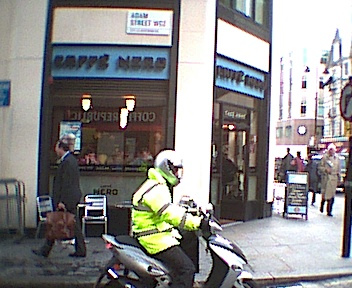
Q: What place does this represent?
A: It represents the coffee shop.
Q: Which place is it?
A: It is a coffee shop.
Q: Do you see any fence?
A: No, there are no fences.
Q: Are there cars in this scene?
A: No, there are no cars.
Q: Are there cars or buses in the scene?
A: No, there are no cars or buses.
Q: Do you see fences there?
A: No, there are no fences.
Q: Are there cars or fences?
A: No, there are no fences or cars.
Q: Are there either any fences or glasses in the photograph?
A: No, there are no fences or glasses.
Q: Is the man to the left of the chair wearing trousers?
A: Yes, the man is wearing trousers.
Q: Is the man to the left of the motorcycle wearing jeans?
A: No, the man is wearing trousers.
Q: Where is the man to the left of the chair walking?
A: The man is walking on the sidewalk.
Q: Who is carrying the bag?
A: The man is carrying the bag.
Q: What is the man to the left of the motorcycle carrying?
A: The man is carrying a bag.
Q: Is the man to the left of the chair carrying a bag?
A: Yes, the man is carrying a bag.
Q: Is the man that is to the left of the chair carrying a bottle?
A: No, the man is carrying a bag.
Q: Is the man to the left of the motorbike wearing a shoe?
A: Yes, the man is wearing a shoe.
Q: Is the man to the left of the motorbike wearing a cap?
A: No, the man is wearing a shoe.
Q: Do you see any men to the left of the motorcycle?
A: Yes, there is a man to the left of the motorcycle.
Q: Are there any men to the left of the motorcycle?
A: Yes, there is a man to the left of the motorcycle.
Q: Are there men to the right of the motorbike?
A: No, the man is to the left of the motorbike.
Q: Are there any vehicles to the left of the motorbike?
A: No, there is a man to the left of the motorbike.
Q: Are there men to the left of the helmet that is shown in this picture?
A: Yes, there is a man to the left of the helmet.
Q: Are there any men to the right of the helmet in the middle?
A: No, the man is to the left of the helmet.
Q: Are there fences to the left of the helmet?
A: No, there is a man to the left of the helmet.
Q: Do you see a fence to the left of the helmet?
A: No, there is a man to the left of the helmet.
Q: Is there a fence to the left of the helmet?
A: No, there is a man to the left of the helmet.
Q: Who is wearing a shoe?
A: The man is wearing a shoe.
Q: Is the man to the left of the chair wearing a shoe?
A: Yes, the man is wearing a shoe.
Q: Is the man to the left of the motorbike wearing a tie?
A: No, the man is wearing a shoe.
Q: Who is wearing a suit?
A: The man is wearing a suit.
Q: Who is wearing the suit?
A: The man is wearing a suit.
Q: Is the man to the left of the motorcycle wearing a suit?
A: Yes, the man is wearing a suit.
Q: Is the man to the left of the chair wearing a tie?
A: No, the man is wearing a suit.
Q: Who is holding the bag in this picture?
A: The man is holding the bag.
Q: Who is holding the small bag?
A: The man is holding the bag.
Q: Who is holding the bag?
A: The man is holding the bag.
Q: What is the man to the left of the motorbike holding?
A: The man is holding the bag.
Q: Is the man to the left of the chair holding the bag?
A: Yes, the man is holding the bag.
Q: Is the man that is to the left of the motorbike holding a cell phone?
A: No, the man is holding the bag.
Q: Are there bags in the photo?
A: Yes, there is a bag.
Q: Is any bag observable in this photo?
A: Yes, there is a bag.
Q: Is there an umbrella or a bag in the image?
A: Yes, there is a bag.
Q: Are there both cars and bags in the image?
A: No, there is a bag but no cars.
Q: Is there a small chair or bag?
A: Yes, there is a small bag.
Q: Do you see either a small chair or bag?
A: Yes, there is a small bag.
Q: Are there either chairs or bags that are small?
A: Yes, the bag is small.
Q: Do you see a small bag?
A: Yes, there is a small bag.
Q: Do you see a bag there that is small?
A: Yes, there is a bag that is small.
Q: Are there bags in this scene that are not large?
A: Yes, there is a small bag.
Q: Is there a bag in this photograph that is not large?
A: Yes, there is a small bag.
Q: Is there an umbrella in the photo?
A: No, there are no umbrellas.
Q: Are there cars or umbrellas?
A: No, there are no umbrellas or cars.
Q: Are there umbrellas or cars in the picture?
A: No, there are no umbrellas or cars.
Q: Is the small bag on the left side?
A: Yes, the bag is on the left of the image.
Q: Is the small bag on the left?
A: Yes, the bag is on the left of the image.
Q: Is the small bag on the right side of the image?
A: No, the bag is on the left of the image.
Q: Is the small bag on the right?
A: No, the bag is on the left of the image.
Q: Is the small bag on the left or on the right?
A: The bag is on the left of the image.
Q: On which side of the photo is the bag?
A: The bag is on the left of the image.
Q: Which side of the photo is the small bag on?
A: The bag is on the left of the image.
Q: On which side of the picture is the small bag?
A: The bag is on the left of the image.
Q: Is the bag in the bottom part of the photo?
A: Yes, the bag is in the bottom of the image.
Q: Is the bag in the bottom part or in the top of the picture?
A: The bag is in the bottom of the image.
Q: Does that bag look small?
A: Yes, the bag is small.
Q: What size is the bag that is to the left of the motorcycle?
A: The bag is small.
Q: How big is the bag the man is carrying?
A: The bag is small.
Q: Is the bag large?
A: No, the bag is small.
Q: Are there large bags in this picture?
A: No, there is a bag but it is small.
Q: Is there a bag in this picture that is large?
A: No, there is a bag but it is small.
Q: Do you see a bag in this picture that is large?
A: No, there is a bag but it is small.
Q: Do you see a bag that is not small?
A: No, there is a bag but it is small.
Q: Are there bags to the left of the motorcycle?
A: Yes, there is a bag to the left of the motorcycle.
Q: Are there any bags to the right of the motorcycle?
A: No, the bag is to the left of the motorcycle.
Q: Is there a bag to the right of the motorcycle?
A: No, the bag is to the left of the motorcycle.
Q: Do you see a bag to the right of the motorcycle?
A: No, the bag is to the left of the motorcycle.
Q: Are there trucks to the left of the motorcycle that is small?
A: No, there is a bag to the left of the motorbike.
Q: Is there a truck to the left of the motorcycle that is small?
A: No, there is a bag to the left of the motorbike.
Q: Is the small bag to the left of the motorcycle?
A: Yes, the bag is to the left of the motorcycle.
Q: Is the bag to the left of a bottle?
A: No, the bag is to the left of the motorcycle.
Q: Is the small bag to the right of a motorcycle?
A: No, the bag is to the left of a motorcycle.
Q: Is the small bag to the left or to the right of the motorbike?
A: The bag is to the left of the motorbike.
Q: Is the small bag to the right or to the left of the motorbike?
A: The bag is to the left of the motorbike.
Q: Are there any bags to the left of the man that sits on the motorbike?
A: Yes, there is a bag to the left of the man.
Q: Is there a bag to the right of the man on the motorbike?
A: No, the bag is to the left of the man.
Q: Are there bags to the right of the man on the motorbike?
A: No, the bag is to the left of the man.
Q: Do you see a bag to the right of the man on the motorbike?
A: No, the bag is to the left of the man.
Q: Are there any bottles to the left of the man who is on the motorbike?
A: No, there is a bag to the left of the man.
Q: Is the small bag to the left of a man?
A: Yes, the bag is to the left of a man.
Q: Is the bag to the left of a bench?
A: No, the bag is to the left of a man.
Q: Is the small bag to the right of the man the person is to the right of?
A: No, the bag is to the left of the man.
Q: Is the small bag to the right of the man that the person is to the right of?
A: No, the bag is to the left of the man.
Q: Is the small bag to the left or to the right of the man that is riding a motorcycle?
A: The bag is to the left of the man.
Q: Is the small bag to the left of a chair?
A: Yes, the bag is to the left of a chair.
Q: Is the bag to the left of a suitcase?
A: No, the bag is to the left of a chair.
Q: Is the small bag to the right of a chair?
A: No, the bag is to the left of a chair.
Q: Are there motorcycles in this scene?
A: Yes, there is a motorcycle.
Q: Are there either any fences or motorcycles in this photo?
A: Yes, there is a motorcycle.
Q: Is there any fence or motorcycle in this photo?
A: Yes, there is a motorcycle.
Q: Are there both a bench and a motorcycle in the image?
A: No, there is a motorcycle but no benches.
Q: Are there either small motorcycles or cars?
A: Yes, there is a small motorcycle.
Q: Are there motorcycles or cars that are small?
A: Yes, the motorcycle is small.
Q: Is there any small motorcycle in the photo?
A: Yes, there is a small motorcycle.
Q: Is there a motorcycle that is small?
A: Yes, there is a motorcycle that is small.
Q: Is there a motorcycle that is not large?
A: Yes, there is a small motorcycle.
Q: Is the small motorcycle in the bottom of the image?
A: Yes, the motorcycle is in the bottom of the image.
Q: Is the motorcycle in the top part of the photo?
A: No, the motorcycle is in the bottom of the image.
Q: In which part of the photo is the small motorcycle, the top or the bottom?
A: The motorbike is in the bottom of the image.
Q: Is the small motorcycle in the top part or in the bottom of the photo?
A: The motorbike is in the bottom of the image.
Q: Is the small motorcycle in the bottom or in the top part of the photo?
A: The motorbike is in the bottom of the image.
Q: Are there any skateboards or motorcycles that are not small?
A: No, there is a motorcycle but it is small.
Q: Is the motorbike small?
A: Yes, the motorbike is small.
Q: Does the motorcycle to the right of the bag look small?
A: Yes, the motorbike is small.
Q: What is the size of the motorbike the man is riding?
A: The motorbike is small.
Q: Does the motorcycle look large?
A: No, the motorcycle is small.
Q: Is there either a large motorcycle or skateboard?
A: No, there is a motorcycle but it is small.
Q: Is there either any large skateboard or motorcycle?
A: No, there is a motorcycle but it is small.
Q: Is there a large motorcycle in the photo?
A: No, there is a motorcycle but it is small.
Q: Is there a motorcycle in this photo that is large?
A: No, there is a motorcycle but it is small.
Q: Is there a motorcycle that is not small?
A: No, there is a motorcycle but it is small.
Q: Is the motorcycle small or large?
A: The motorcycle is small.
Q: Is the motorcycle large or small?
A: The motorcycle is small.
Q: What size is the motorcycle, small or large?
A: The motorcycle is small.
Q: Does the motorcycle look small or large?
A: The motorcycle is small.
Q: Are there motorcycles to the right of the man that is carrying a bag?
A: Yes, there is a motorcycle to the right of the man.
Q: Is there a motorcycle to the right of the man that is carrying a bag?
A: Yes, there is a motorcycle to the right of the man.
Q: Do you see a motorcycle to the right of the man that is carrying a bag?
A: Yes, there is a motorcycle to the right of the man.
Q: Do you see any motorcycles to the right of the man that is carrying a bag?
A: Yes, there is a motorcycle to the right of the man.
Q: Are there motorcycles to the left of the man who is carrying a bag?
A: No, the motorcycle is to the right of the man.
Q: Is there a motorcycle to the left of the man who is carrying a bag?
A: No, the motorcycle is to the right of the man.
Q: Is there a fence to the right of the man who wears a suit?
A: No, there is a motorcycle to the right of the man.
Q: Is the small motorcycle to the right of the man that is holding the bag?
A: Yes, the motorcycle is to the right of the man.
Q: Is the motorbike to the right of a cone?
A: No, the motorbike is to the right of the man.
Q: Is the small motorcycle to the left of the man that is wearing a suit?
A: No, the motorcycle is to the right of the man.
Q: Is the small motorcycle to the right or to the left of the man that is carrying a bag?
A: The motorcycle is to the right of the man.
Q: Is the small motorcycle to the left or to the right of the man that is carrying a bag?
A: The motorcycle is to the right of the man.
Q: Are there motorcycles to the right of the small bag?
A: Yes, there is a motorcycle to the right of the bag.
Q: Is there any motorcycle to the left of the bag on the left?
A: No, the motorcycle is to the right of the bag.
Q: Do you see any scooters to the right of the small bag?
A: No, there is a motorcycle to the right of the bag.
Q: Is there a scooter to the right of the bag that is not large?
A: No, there is a motorcycle to the right of the bag.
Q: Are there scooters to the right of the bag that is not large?
A: No, there is a motorcycle to the right of the bag.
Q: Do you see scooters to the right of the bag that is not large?
A: No, there is a motorcycle to the right of the bag.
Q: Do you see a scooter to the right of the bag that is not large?
A: No, there is a motorcycle to the right of the bag.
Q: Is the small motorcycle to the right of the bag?
A: Yes, the motorcycle is to the right of the bag.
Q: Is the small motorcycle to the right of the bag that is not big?
A: Yes, the motorcycle is to the right of the bag.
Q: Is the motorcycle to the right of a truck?
A: No, the motorcycle is to the right of the bag.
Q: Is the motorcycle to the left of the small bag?
A: No, the motorcycle is to the right of the bag.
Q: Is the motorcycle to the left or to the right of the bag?
A: The motorcycle is to the right of the bag.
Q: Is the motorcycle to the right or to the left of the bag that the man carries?
A: The motorcycle is to the right of the bag.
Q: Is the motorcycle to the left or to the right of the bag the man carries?
A: The motorcycle is to the right of the bag.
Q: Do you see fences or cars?
A: No, there are no fences or cars.